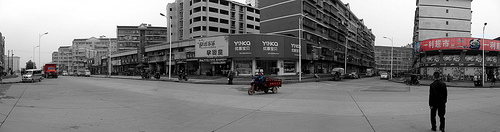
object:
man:
[251, 72, 267, 91]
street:
[0, 75, 499, 130]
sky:
[0, 0, 499, 68]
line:
[208, 89, 302, 132]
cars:
[76, 70, 90, 77]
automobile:
[22, 69, 44, 82]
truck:
[43, 64, 57, 78]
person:
[428, 72, 448, 131]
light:
[160, 13, 165, 16]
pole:
[169, 7, 172, 80]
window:
[445, 21, 447, 25]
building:
[413, 0, 469, 42]